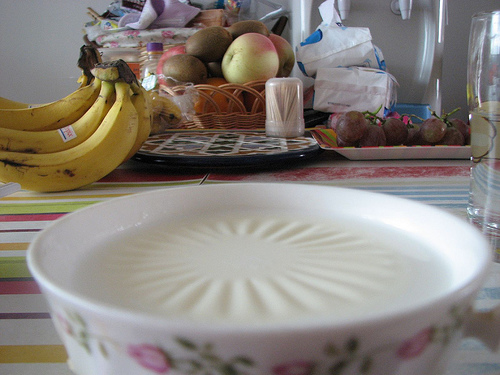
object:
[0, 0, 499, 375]
area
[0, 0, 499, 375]
kitchen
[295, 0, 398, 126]
bags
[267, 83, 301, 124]
toothpicks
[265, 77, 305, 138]
container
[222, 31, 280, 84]
apple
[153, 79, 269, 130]
basket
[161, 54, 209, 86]
kiwi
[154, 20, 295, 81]
fruits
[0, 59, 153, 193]
bananas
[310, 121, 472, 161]
plate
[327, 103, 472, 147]
fruits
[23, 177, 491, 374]
dispenser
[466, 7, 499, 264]
glass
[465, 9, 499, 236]
drinking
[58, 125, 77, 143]
sticker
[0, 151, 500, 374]
table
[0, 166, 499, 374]
cloth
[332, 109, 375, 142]
grape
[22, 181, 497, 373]
bowl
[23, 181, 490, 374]
dish